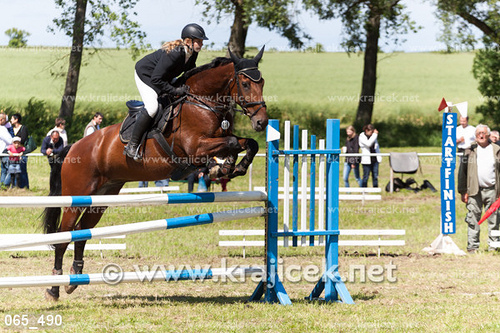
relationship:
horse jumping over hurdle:
[46, 46, 270, 304] [1, 118, 358, 304]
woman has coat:
[339, 126, 365, 188] [345, 135, 361, 166]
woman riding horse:
[125, 23, 209, 164] [46, 46, 270, 304]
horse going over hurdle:
[46, 46, 270, 304] [1, 118, 358, 304]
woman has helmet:
[125, 23, 209, 164] [180, 24, 210, 39]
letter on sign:
[446, 113, 454, 125] [443, 112, 455, 236]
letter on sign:
[444, 124, 455, 137] [443, 112, 455, 236]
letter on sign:
[443, 145, 452, 158] [443, 112, 455, 236]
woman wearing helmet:
[125, 23, 209, 164] [180, 24, 210, 39]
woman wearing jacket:
[125, 23, 209, 164] [133, 42, 199, 93]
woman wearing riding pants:
[125, 23, 209, 164] [132, 69, 158, 116]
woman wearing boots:
[125, 23, 209, 164] [126, 108, 154, 161]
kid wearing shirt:
[3, 134, 27, 190] [6, 146, 27, 163]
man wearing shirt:
[456, 122, 500, 253] [475, 145, 496, 187]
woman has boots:
[125, 23, 209, 164] [126, 108, 154, 161]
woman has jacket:
[125, 23, 209, 164] [133, 42, 199, 93]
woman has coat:
[360, 124, 384, 186] [359, 133, 382, 164]